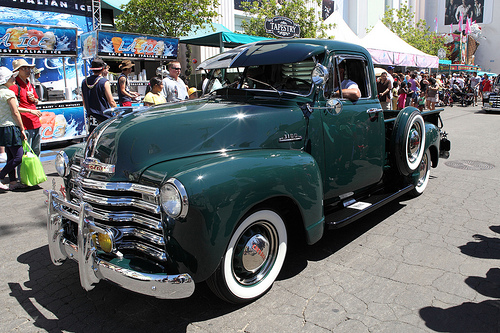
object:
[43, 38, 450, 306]
car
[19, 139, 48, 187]
bag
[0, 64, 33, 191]
person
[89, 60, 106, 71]
baseball cap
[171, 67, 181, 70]
sunglasses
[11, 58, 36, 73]
hat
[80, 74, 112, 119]
shirt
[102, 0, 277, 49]
awning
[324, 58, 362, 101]
man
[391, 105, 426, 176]
tire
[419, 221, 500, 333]
shadows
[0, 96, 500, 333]
road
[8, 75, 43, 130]
shirt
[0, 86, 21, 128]
shirt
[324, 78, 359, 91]
shirt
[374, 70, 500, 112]
people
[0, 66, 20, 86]
hat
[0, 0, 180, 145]
stall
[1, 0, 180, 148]
ice cream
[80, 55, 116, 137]
man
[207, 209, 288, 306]
tires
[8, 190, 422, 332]
shadow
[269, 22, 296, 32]
tapestry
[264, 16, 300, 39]
sign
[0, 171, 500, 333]
cracks